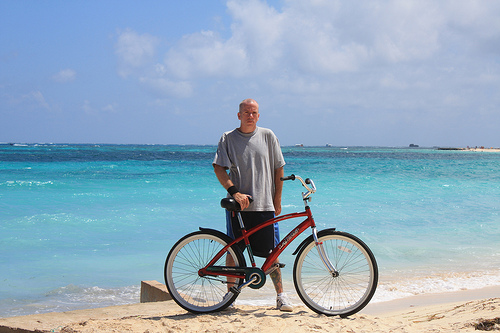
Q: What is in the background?
A: The ocean.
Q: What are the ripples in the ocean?
A: Waves.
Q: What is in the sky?
A: Clouds.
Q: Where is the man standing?
A: On the beach.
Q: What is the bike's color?
A: Red and Black.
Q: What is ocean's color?
A: Blue.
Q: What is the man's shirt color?
A: Gray.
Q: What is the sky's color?
A: Blue.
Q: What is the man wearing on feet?
A: Tennis shoes.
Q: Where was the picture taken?
A: At the beach.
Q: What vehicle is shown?
A: A bicycle.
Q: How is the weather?
A: Partly cloudy.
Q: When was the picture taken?
A: During daylight hours.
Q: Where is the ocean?
A: Behind the man.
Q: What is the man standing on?
A: Sand.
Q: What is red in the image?
A: Bicycle.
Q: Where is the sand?
A: On the beach.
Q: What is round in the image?
A: Bicycle tires.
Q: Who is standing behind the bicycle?
A: A man.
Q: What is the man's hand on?
A: Bike seat.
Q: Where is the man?
A: Beach.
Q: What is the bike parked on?
A: Sand.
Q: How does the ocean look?
A: Clear.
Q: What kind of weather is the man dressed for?
A: Warm.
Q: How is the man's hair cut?
A: Shaved.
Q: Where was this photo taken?
A: At the beach.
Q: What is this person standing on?
A: Sand.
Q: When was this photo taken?
A: Outside, during the daytime.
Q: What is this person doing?
A: Standing near a bike.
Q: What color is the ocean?
A: Blue.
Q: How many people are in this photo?
A: One.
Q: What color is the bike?
A: Red.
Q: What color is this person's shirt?
A: Gray.